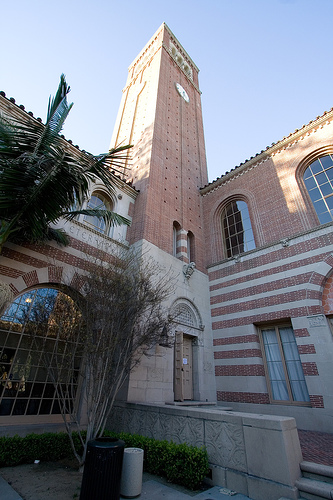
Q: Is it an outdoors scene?
A: Yes, it is outdoors.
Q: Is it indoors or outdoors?
A: It is outdoors.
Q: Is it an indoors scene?
A: No, it is outdoors.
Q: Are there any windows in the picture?
A: Yes, there is a window.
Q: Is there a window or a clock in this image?
A: Yes, there is a window.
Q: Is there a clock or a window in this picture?
A: Yes, there is a window.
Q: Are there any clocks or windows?
A: Yes, there is a window.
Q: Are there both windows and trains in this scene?
A: No, there is a window but no trains.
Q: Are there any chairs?
A: No, there are no chairs.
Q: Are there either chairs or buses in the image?
A: No, there are no chairs or buses.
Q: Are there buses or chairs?
A: No, there are no chairs or buses.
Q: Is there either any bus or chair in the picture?
A: No, there are no chairs or buses.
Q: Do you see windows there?
A: Yes, there is a window.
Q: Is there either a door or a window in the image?
A: Yes, there is a window.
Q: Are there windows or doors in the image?
A: Yes, there is a window.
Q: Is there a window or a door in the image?
A: Yes, there is a window.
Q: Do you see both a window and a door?
A: Yes, there are both a window and a door.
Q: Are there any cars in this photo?
A: No, there are no cars.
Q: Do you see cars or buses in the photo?
A: No, there are no cars or buses.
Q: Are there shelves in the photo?
A: No, there are no shelves.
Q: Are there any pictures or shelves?
A: No, there are no shelves or pictures.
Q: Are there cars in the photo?
A: No, there are no cars.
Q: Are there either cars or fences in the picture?
A: No, there are no cars or fences.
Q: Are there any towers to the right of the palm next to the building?
A: Yes, there is a tower to the right of the palm tree.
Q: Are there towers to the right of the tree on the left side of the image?
A: Yes, there is a tower to the right of the palm tree.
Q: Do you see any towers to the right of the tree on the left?
A: Yes, there is a tower to the right of the palm tree.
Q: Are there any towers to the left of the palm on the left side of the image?
A: No, the tower is to the right of the palm tree.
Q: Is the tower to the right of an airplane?
A: No, the tower is to the right of the palm.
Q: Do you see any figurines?
A: No, there are no figurines.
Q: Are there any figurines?
A: No, there are no figurines.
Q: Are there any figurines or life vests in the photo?
A: No, there are no figurines or life vests.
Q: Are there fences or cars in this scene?
A: No, there are no fences or cars.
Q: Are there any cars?
A: No, there are no cars.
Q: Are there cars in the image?
A: No, there are no cars.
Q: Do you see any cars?
A: No, there are no cars.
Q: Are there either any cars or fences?
A: No, there are no cars or fences.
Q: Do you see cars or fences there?
A: No, there are no cars or fences.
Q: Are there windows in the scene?
A: Yes, there is a window.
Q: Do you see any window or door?
A: Yes, there is a window.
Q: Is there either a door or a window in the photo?
A: Yes, there is a window.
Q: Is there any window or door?
A: Yes, there is a window.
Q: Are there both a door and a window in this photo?
A: Yes, there are both a window and a door.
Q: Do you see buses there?
A: No, there are no buses.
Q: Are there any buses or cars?
A: No, there are no buses or cars.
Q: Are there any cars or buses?
A: No, there are no buses or cars.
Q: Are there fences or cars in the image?
A: No, there are no cars or fences.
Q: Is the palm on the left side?
A: Yes, the palm is on the left of the image.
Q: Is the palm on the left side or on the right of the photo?
A: The palm is on the left of the image.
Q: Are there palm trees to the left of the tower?
A: Yes, there is a palm tree to the left of the tower.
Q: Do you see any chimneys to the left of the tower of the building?
A: No, there is a palm tree to the left of the tower.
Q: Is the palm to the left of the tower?
A: Yes, the palm is to the left of the tower.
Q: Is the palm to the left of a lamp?
A: No, the palm is to the left of the tower.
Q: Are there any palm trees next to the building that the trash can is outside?
A: Yes, there is a palm tree next to the building.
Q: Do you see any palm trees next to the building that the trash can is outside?
A: Yes, there is a palm tree next to the building.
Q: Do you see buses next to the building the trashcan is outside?
A: No, there is a palm tree next to the building.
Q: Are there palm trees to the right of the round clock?
A: No, the palm tree is to the left of the clock.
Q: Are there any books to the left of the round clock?
A: No, there is a palm tree to the left of the clock.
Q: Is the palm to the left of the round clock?
A: Yes, the palm is to the left of the clock.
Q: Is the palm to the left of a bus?
A: No, the palm is to the left of the clock.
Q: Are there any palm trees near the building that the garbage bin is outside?
A: Yes, there is a palm tree near the building.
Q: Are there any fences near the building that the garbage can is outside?
A: No, there is a palm tree near the building.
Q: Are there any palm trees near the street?
A: Yes, there is a palm tree near the street.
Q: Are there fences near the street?
A: No, there is a palm tree near the street.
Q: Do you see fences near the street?
A: No, there is a palm tree near the street.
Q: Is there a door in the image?
A: Yes, there is a door.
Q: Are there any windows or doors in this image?
A: Yes, there is a door.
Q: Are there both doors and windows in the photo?
A: Yes, there are both a door and windows.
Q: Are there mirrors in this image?
A: No, there are no mirrors.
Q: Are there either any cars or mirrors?
A: No, there are no mirrors or cars.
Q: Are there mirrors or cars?
A: No, there are no mirrors or cars.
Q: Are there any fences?
A: No, there are no fences.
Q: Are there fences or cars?
A: No, there are no fences or cars.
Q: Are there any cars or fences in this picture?
A: No, there are no fences or cars.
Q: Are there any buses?
A: No, there are no buses.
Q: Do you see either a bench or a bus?
A: No, there are no buses or benches.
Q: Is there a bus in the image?
A: No, there are no buses.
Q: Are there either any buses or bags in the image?
A: No, there are no buses or bags.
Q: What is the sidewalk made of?
A: The sidewalk is made of brick.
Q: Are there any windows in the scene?
A: Yes, there is a window.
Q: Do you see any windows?
A: Yes, there is a window.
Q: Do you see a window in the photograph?
A: Yes, there is a window.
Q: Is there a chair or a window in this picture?
A: Yes, there is a window.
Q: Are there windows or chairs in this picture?
A: Yes, there is a window.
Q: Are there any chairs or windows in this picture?
A: Yes, there is a window.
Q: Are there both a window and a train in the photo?
A: No, there is a window but no trains.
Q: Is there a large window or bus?
A: Yes, there is a large window.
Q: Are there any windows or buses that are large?
A: Yes, the window is large.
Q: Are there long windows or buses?
A: Yes, there is a long window.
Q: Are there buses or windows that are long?
A: Yes, the window is long.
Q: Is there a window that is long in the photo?
A: Yes, there is a long window.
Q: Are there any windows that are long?
A: Yes, there is a window that is long.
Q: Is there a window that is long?
A: Yes, there is a window that is long.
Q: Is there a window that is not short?
A: Yes, there is a long window.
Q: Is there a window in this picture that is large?
A: Yes, there is a large window.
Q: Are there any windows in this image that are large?
A: Yes, there is a window that is large.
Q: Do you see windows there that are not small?
A: Yes, there is a large window.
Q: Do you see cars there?
A: No, there are no cars.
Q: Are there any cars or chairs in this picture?
A: No, there are no cars or chairs.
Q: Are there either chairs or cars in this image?
A: No, there are no cars or chairs.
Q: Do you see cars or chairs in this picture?
A: No, there are no cars or chairs.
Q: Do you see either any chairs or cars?
A: No, there are no cars or chairs.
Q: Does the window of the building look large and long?
A: Yes, the window is large and long.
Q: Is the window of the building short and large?
A: No, the window is large but long.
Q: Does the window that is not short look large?
A: Yes, the window is large.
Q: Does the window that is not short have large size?
A: Yes, the window is large.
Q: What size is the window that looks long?
A: The window is large.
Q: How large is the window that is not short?
A: The window is large.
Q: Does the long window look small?
A: No, the window is large.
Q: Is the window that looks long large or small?
A: The window is large.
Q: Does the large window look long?
A: Yes, the window is long.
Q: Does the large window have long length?
A: Yes, the window is long.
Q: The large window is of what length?
A: The window is long.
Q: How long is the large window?
A: The window is long.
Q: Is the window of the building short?
A: No, the window is long.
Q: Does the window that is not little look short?
A: No, the window is long.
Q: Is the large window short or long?
A: The window is long.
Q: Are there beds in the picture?
A: No, there are no beds.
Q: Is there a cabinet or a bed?
A: No, there are no beds or cabinets.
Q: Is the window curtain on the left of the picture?
A: No, the curtain is on the right of the image.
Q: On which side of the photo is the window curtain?
A: The curtain is on the right of the image.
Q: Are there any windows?
A: Yes, there is a window.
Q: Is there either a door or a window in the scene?
A: Yes, there is a window.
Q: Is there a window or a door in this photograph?
A: Yes, there is a window.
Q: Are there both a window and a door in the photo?
A: Yes, there are both a window and a door.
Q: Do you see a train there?
A: No, there are no trains.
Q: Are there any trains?
A: No, there are no trains.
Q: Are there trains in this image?
A: No, there are no trains.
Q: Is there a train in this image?
A: No, there are no trains.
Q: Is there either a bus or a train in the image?
A: No, there are no trains or buses.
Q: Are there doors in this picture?
A: Yes, there is a door.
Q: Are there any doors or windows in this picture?
A: Yes, there is a door.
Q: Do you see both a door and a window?
A: Yes, there are both a door and a window.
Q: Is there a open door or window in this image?
A: Yes, there is an open door.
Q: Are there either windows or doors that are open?
A: Yes, the door is open.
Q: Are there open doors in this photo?
A: Yes, there is an open door.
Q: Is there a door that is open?
A: Yes, there is a door that is open.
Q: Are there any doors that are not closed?
A: Yes, there is a open door.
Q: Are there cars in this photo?
A: No, there are no cars.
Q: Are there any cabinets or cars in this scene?
A: No, there are no cars or cabinets.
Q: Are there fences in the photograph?
A: No, there are no fences.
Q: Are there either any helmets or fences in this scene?
A: No, there are no fences or helmets.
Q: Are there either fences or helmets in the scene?
A: No, there are no fences or helmets.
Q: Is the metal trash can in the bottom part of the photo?
A: Yes, the trashcan is in the bottom of the image.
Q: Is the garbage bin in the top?
A: No, the garbage bin is in the bottom of the image.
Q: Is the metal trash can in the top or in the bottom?
A: The trash can is in the bottom of the image.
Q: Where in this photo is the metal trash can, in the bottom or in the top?
A: The trash can is in the bottom of the image.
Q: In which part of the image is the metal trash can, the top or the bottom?
A: The trash can is in the bottom of the image.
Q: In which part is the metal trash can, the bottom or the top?
A: The trash can is in the bottom of the image.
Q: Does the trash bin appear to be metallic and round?
A: Yes, the trash bin is metallic and round.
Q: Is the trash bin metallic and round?
A: Yes, the trash bin is metallic and round.